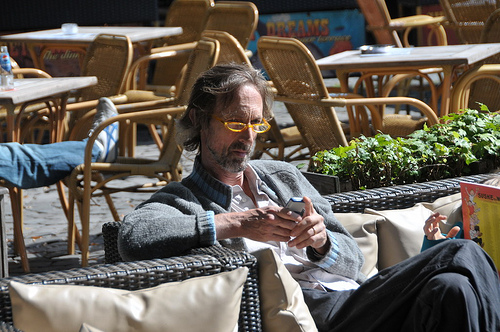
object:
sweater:
[114, 153, 368, 283]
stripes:
[103, 127, 115, 163]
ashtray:
[356, 45, 396, 55]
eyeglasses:
[213, 119, 272, 133]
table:
[0, 25, 183, 79]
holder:
[58, 22, 78, 36]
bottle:
[0, 44, 15, 92]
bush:
[294, 101, 499, 191]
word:
[265, 18, 329, 38]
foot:
[88, 96, 121, 164]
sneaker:
[84, 96, 119, 164]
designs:
[101, 121, 120, 163]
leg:
[0, 138, 100, 189]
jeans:
[0, 139, 100, 189]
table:
[0, 75, 99, 148]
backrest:
[72, 33, 134, 105]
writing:
[316, 35, 350, 43]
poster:
[243, 9, 366, 58]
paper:
[460, 182, 500, 277]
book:
[456, 179, 499, 277]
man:
[117, 59, 500, 331]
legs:
[334, 236, 500, 331]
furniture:
[100, 173, 500, 267]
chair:
[0, 242, 268, 332]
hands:
[239, 203, 303, 244]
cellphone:
[281, 197, 306, 222]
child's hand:
[422, 211, 460, 243]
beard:
[203, 139, 258, 174]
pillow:
[325, 210, 387, 285]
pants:
[325, 237, 499, 330]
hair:
[172, 62, 274, 152]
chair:
[64, 38, 221, 269]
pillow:
[5, 265, 255, 331]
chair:
[255, 32, 441, 155]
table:
[315, 41, 500, 141]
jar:
[59, 21, 79, 36]